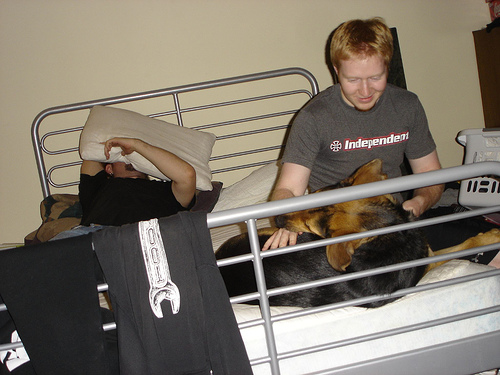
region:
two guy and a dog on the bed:
[47, 23, 464, 290]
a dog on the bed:
[213, 160, 451, 302]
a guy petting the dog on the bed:
[219, 8, 453, 320]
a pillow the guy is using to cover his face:
[77, 102, 224, 190]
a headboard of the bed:
[206, 55, 315, 102]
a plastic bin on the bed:
[447, 117, 495, 204]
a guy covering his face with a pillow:
[63, 103, 217, 231]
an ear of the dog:
[328, 230, 360, 273]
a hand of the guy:
[259, 225, 305, 250]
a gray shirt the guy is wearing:
[279, 92, 439, 169]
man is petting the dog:
[228, 18, 498, 337]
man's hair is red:
[303, 4, 416, 79]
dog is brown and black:
[208, 171, 438, 304]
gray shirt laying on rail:
[87, 213, 254, 369]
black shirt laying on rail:
[1, 231, 129, 369]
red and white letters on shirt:
[334, 123, 415, 151]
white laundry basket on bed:
[450, 113, 499, 209]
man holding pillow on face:
[65, 100, 222, 204]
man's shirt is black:
[70, 162, 207, 252]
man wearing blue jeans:
[41, 208, 109, 260]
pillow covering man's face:
[75, 101, 197, 226]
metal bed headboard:
[30, 64, 320, 207]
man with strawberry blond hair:
[260, 14, 448, 250]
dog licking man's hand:
[213, 156, 498, 310]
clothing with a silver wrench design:
[92, 216, 254, 373]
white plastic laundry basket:
[455, 126, 499, 222]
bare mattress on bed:
[242, 262, 497, 374]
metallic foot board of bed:
[0, 157, 497, 371]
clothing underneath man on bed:
[35, 191, 82, 242]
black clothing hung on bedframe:
[0, 231, 107, 372]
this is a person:
[60, 120, 221, 241]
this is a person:
[271, 17, 446, 242]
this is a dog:
[217, 185, 457, 320]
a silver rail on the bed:
[237, 152, 494, 210]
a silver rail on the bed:
[262, 192, 494, 257]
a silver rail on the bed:
[275, 241, 497, 298]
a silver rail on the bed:
[281, 265, 496, 320]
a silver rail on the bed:
[282, 303, 497, 359]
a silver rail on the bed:
[35, 60, 312, 128]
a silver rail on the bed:
[187, 88, 319, 120]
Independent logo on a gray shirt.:
[326, 132, 420, 152]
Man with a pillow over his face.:
[79, 105, 224, 219]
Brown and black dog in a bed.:
[232, 164, 457, 306]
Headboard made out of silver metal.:
[31, 66, 321, 215]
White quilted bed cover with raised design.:
[258, 314, 498, 336]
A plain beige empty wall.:
[12, 17, 311, 65]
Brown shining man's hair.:
[327, 17, 398, 78]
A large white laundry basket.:
[449, 131, 498, 207]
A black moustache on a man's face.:
[118, 160, 140, 180]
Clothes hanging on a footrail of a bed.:
[2, 205, 252, 373]